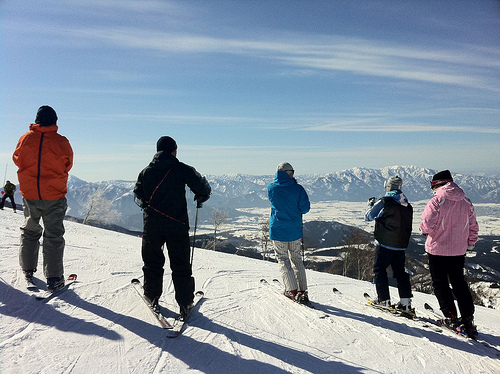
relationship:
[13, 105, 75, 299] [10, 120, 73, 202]
man wearing jacket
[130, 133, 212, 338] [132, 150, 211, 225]
man wearing jacket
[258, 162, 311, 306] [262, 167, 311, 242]
person wearing jacket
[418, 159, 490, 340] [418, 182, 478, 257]
person in a coat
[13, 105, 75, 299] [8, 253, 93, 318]
man on skis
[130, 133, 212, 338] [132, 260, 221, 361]
man on skis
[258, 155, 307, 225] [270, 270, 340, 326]
person on skis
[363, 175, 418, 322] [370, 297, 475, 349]
skier on skis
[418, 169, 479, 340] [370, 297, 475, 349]
person on skis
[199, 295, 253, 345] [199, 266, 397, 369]
skitracks in snow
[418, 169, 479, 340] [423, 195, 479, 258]
person in a jacket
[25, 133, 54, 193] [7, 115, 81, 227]
stripe down back of a jacket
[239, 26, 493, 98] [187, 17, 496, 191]
clouds across sky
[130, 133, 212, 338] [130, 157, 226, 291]
man in a ski outfit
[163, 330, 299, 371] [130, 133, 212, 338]
shadows of man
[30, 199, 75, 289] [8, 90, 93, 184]
leg of a person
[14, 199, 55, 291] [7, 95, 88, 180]
leg of a person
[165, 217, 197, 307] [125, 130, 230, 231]
leg of a person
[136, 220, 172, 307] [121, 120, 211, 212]
leg of a person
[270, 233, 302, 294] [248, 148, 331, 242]
leg of a person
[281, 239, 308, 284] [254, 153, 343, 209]
leg of a person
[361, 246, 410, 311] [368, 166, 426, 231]
leg of a person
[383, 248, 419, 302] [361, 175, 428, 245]
leg of a person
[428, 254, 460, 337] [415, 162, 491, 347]
leg of person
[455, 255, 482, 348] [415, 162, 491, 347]
leg of person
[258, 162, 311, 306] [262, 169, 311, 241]
person in jacket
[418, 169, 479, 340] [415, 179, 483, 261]
person in coat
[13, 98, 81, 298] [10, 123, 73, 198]
man in jacket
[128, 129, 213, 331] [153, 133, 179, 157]
man with hat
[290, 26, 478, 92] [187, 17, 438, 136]
clouds in sky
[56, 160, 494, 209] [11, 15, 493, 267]
mountain range in background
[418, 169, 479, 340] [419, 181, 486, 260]
person in jacket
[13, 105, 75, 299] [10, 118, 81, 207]
man in jacket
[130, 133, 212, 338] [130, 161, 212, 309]
man in ski outfit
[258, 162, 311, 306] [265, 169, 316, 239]
person in jacket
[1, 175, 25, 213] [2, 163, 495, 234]
man in distance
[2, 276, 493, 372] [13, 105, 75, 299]
shadows from man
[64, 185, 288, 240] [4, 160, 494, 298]
trees in background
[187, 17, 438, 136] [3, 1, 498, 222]
sky in background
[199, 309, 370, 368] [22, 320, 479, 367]
snow on ground